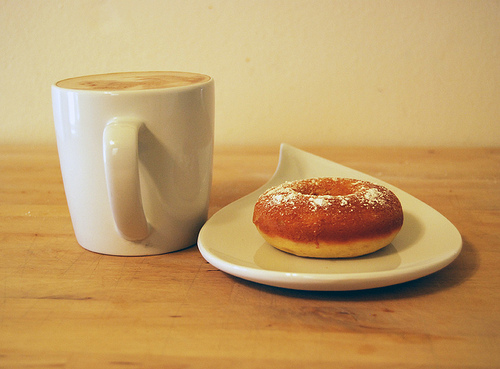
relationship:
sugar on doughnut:
[254, 177, 398, 213] [251, 175, 406, 262]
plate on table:
[196, 140, 466, 294] [1, 138, 500, 368]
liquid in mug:
[55, 70, 213, 92] [49, 69, 217, 258]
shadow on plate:
[253, 211, 428, 277] [196, 140, 466, 294]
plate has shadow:
[196, 140, 466, 294] [253, 211, 428, 277]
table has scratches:
[1, 138, 500, 368] [10, 215, 280, 357]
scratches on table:
[10, 215, 280, 357] [1, 138, 500, 368]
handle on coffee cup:
[101, 118, 154, 242] [49, 69, 217, 258]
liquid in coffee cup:
[55, 70, 213, 92] [49, 69, 217, 258]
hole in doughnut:
[294, 187, 360, 198] [251, 175, 406, 262]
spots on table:
[169, 305, 395, 321] [1, 138, 500, 368]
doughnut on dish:
[251, 175, 406, 262] [196, 140, 466, 294]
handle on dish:
[101, 118, 154, 242] [49, 69, 217, 258]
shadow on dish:
[253, 211, 428, 277] [196, 140, 466, 294]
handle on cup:
[101, 118, 154, 242] [49, 69, 217, 258]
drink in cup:
[55, 70, 213, 92] [49, 69, 217, 258]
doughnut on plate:
[251, 175, 406, 262] [196, 140, 466, 294]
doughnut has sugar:
[251, 175, 406, 262] [254, 177, 398, 213]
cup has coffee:
[49, 69, 217, 258] [55, 70, 213, 92]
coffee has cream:
[55, 70, 213, 92] [57, 71, 145, 90]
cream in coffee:
[57, 71, 145, 90] [55, 70, 213, 92]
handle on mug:
[101, 118, 154, 242] [49, 69, 217, 258]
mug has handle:
[49, 69, 217, 258] [101, 118, 154, 242]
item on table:
[49, 69, 217, 258] [1, 138, 500, 368]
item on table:
[196, 140, 466, 294] [1, 138, 500, 368]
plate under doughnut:
[196, 140, 466, 294] [251, 175, 406, 262]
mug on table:
[49, 69, 217, 258] [1, 138, 500, 368]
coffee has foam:
[55, 70, 213, 92] [57, 71, 145, 90]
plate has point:
[196, 140, 466, 294] [274, 141, 336, 164]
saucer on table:
[196, 140, 466, 294] [1, 138, 500, 368]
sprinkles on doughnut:
[254, 177, 398, 213] [251, 175, 406, 262]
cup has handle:
[49, 69, 217, 258] [101, 118, 154, 242]